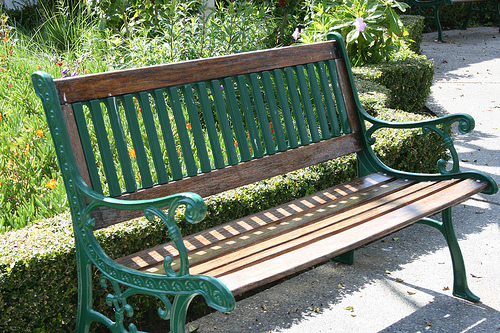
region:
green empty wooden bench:
[22, 47, 484, 309]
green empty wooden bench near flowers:
[23, 65, 488, 325]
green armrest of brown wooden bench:
[26, 67, 236, 328]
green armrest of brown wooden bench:
[310, 26, 492, 317]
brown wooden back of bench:
[31, 45, 378, 177]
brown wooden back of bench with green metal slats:
[28, 58, 397, 188]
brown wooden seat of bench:
[88, 162, 468, 279]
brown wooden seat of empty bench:
[94, 177, 474, 295]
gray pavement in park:
[404, 20, 494, 105]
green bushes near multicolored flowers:
[43, 11, 287, 103]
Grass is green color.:
[6, 42, 45, 70]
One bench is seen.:
[45, 68, 462, 310]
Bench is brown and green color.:
[54, 78, 494, 322]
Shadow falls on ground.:
[173, 245, 498, 327]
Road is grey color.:
[343, 251, 440, 328]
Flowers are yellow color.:
[6, 115, 58, 196]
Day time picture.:
[18, 32, 487, 324]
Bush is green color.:
[18, 252, 73, 317]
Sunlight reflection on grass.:
[18, 38, 77, 85]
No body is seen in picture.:
[27, 44, 470, 311]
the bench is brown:
[2, 47, 490, 322]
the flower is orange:
[38, 171, 57, 210]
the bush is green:
[358, 70, 430, 135]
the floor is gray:
[431, 39, 459, 70]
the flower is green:
[343, 17, 385, 44]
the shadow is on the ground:
[304, 282, 430, 330]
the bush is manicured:
[6, 233, 83, 320]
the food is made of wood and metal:
[63, 50, 366, 183]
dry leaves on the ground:
[342, 272, 417, 327]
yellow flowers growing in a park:
[28, 123, 44, 151]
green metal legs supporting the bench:
[429, 219, 476, 307]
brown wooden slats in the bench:
[224, 221, 296, 271]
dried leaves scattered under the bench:
[308, 277, 390, 323]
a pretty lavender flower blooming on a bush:
[354, 3, 380, 38]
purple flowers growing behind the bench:
[63, 59, 83, 74]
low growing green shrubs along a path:
[366, 63, 414, 117]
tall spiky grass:
[40, 14, 90, 38]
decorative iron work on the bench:
[109, 271, 154, 328]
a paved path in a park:
[459, 60, 476, 111]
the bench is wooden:
[23, 73, 470, 287]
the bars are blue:
[93, 101, 334, 156]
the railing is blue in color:
[31, 95, 213, 322]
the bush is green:
[14, 216, 67, 332]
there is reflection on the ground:
[313, 271, 438, 331]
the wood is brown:
[258, 201, 394, 255]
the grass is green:
[10, 100, 54, 213]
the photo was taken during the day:
[4, 6, 494, 331]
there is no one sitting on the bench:
[39, 61, 496, 264]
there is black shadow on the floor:
[424, 291, 494, 331]